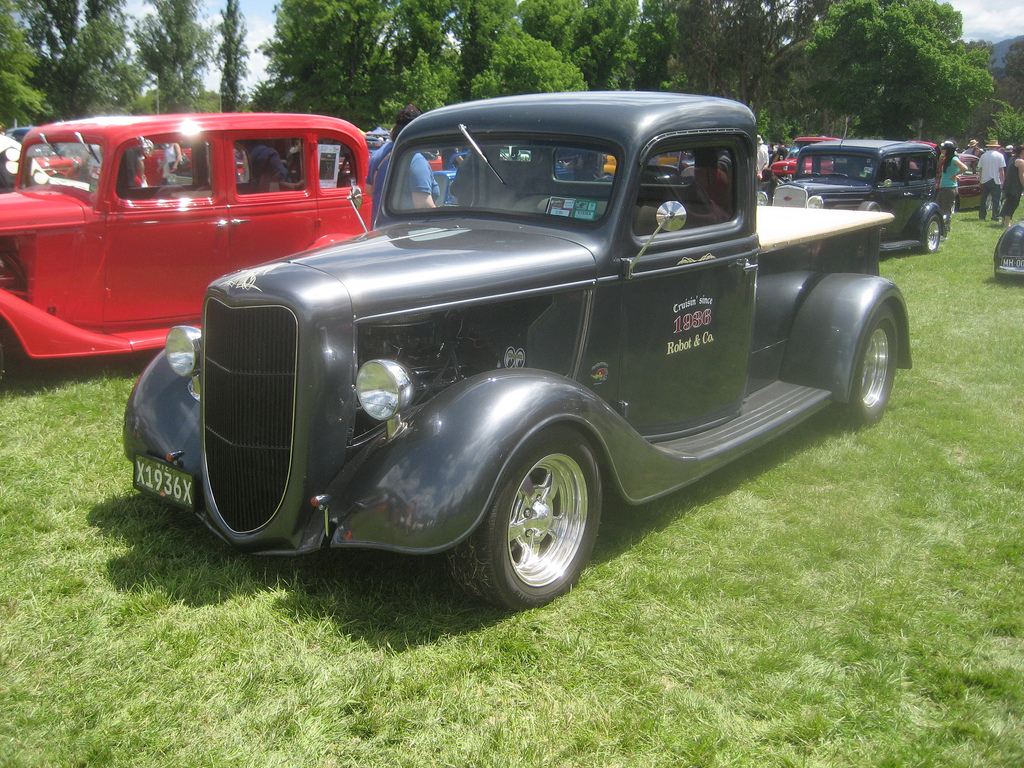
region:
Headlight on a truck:
[345, 351, 421, 447]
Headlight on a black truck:
[345, 351, 418, 446]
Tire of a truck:
[443, 415, 608, 608]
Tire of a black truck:
[449, 412, 615, 613]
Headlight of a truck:
[153, 318, 215, 396]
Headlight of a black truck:
[155, 320, 219, 407]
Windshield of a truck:
[386, 134, 630, 234]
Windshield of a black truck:
[389, 128, 623, 236]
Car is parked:
[83, 51, 938, 614]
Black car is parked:
[103, 73, 932, 614]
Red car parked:
[0, 103, 402, 391]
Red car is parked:
[0, 84, 397, 414]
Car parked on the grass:
[115, 59, 938, 613]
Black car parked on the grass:
[76, 70, 952, 608]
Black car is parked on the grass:
[109, 59, 929, 619]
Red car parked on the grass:
[0, 96, 387, 410]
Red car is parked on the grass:
[0, 90, 400, 417]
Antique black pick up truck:
[118, 91, 921, 601]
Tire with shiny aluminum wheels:
[471, 421, 617, 624]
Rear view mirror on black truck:
[633, 189, 695, 273]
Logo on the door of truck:
[642, 277, 723, 372]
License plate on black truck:
[125, 451, 199, 516]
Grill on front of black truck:
[200, 296, 302, 540]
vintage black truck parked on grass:
[117, 88, 920, 623]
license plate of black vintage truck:
[123, 451, 197, 510]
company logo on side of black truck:
[661, 290, 719, 360]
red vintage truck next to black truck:
[0, 104, 406, 387]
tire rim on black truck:
[499, 446, 594, 590]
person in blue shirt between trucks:
[363, 102, 455, 229]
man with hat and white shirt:
[970, 138, 1008, 227]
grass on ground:
[0, 171, 1023, 766]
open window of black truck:
[620, 124, 748, 243]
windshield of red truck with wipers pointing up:
[25, 124, 106, 194]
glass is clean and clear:
[392, 142, 614, 226]